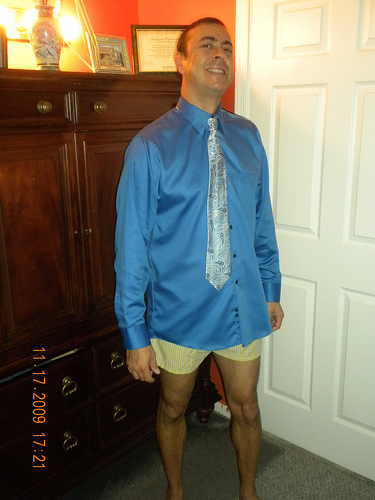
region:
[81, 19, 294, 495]
man standing in room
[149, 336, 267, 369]
shorts on the man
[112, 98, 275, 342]
shirt on the man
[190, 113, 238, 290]
tie on the man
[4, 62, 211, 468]
cabinets and drawers in room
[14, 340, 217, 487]
drawers on bottom of cabinets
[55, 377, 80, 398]
handle on the drawer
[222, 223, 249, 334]
buttons on man's shirt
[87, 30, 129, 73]
image on top of cabinets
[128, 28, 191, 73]
recognition paper in glass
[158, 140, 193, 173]
the shirt is blue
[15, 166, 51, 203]
the dresser is brown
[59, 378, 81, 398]
the handle is gold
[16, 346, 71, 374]
the drawer is cracked open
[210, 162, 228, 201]
the tie is silver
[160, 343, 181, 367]
the shorts are yellow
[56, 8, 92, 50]
the light is on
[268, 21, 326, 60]
the door is white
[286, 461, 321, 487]
the carpet is gray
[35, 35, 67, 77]
the lamp is onn the dresser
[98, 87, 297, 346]
the shirt is blue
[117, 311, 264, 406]
the short is yellow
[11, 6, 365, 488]
Man standing in his bedroom.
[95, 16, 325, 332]
European man wearing a blue oxford shirt and a gray paisley tie.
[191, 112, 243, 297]
Light gray paisley tie.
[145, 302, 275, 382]
Man wearing beige shorts.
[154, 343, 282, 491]
Man's muscular long legs.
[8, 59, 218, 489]
Large wooden clothing cabinet.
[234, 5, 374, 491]
White decorative bedroom door.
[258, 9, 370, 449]
Decorative rectangular indentations of a bedroom door.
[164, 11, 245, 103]
Face of a smiling man.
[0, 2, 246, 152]
Orange wall of a man's bedroom.